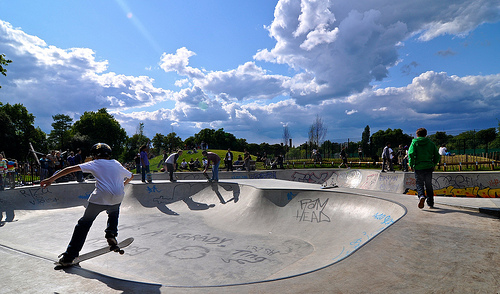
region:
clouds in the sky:
[165, 53, 264, 123]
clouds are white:
[158, 51, 268, 121]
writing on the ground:
[172, 220, 275, 276]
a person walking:
[404, 128, 441, 210]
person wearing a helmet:
[91, 139, 112, 154]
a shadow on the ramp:
[181, 193, 212, 215]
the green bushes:
[325, 137, 361, 149]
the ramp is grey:
[392, 242, 457, 292]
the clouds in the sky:
[69, 61, 139, 107]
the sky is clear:
[46, 12, 123, 42]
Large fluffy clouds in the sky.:
[11, 10, 479, 136]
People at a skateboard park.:
[9, 48, 471, 292]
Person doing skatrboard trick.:
[34, 134, 145, 278]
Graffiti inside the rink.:
[21, 175, 377, 291]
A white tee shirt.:
[71, 155, 143, 212]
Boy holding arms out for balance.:
[40, 136, 142, 231]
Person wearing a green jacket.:
[406, 123, 446, 175]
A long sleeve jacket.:
[407, 133, 443, 175]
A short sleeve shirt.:
[76, 150, 134, 209]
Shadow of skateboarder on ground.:
[71, 268, 169, 291]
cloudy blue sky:
[2, 0, 499, 153]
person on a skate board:
[34, 137, 141, 267]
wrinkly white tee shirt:
[77, 150, 132, 204]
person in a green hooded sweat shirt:
[405, 127, 445, 212]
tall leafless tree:
[302, 114, 332, 150]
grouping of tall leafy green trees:
[355, 120, 499, 159]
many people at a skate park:
[0, 148, 499, 293]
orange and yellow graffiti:
[404, 182, 499, 201]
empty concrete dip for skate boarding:
[2, 175, 407, 286]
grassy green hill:
[143, 140, 259, 167]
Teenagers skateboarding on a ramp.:
[27, 119, 464, 282]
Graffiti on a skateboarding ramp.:
[275, 179, 335, 232]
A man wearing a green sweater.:
[399, 122, 444, 211]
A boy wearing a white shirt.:
[41, 138, 139, 269]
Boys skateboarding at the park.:
[133, 137, 232, 197]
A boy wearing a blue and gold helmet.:
[39, 136, 136, 278]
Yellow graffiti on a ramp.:
[403, 164, 497, 202]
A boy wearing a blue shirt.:
[133, 139, 161, 187]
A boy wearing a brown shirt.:
[195, 145, 231, 194]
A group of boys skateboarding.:
[27, 123, 306, 279]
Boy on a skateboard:
[48, 228, 145, 275]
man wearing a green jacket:
[404, 134, 444, 172]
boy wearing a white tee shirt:
[79, 155, 134, 210]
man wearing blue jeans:
[416, 168, 441, 201]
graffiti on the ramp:
[295, 190, 338, 231]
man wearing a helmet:
[89, 138, 109, 164]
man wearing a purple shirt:
[134, 148, 152, 165]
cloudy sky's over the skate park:
[254, 6, 389, 108]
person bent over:
[203, 152, 225, 164]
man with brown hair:
[416, 121, 428, 138]